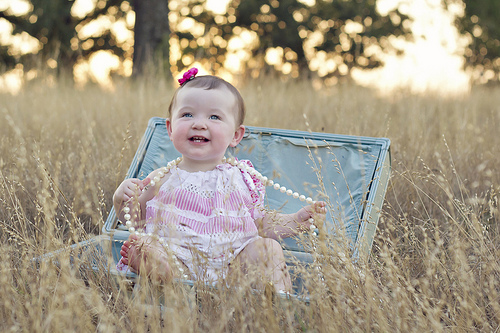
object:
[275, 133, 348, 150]
torn interior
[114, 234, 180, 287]
foot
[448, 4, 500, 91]
tree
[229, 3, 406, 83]
tree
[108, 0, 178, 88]
tree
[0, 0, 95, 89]
tree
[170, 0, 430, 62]
foliage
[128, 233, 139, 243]
toes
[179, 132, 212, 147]
smile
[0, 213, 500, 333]
yellow straw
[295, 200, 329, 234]
hand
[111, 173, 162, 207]
hand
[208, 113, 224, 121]
blue eye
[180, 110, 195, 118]
blue eye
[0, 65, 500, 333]
wheat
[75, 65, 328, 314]
baby grass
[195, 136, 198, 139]
teeth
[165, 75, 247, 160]
head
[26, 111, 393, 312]
blue suitcase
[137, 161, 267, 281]
pink clothing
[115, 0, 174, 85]
tree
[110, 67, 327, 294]
baby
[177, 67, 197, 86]
bow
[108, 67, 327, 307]
child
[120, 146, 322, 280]
pearl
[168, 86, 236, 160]
face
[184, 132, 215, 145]
mouth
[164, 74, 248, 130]
hair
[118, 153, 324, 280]
necklace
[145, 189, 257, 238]
pattern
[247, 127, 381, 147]
edge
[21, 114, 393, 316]
suitcase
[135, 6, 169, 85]
bark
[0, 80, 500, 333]
field